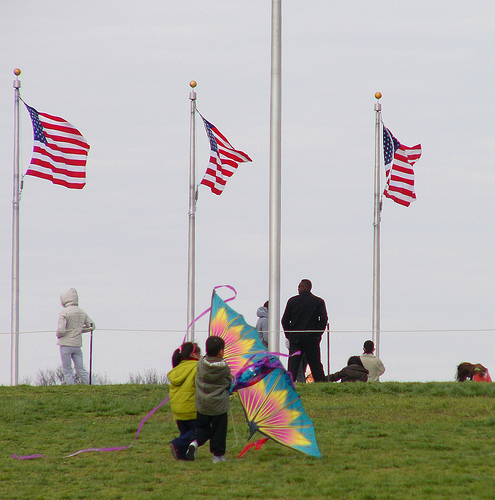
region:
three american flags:
[12, 67, 432, 212]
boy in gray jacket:
[196, 336, 228, 455]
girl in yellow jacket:
[166, 344, 197, 452]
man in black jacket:
[281, 278, 329, 381]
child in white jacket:
[55, 288, 93, 387]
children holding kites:
[166, 285, 326, 463]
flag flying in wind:
[367, 85, 422, 378]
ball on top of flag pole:
[190, 81, 196, 88]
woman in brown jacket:
[337, 355, 368, 382]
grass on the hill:
[7, 388, 490, 494]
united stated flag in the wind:
[13, 91, 96, 187]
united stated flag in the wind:
[190, 103, 269, 205]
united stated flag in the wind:
[375, 116, 430, 218]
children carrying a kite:
[160, 276, 319, 474]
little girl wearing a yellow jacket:
[167, 341, 201, 464]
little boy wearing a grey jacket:
[179, 336, 234, 463]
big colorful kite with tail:
[213, 282, 328, 458]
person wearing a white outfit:
[49, 284, 102, 387]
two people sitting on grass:
[332, 338, 396, 387]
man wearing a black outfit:
[274, 272, 340, 384]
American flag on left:
[22, 103, 91, 189]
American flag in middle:
[198, 116, 253, 196]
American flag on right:
[381, 124, 422, 207]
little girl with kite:
[167, 289, 273, 458]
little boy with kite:
[185, 333, 322, 463]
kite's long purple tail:
[11, 391, 167, 459]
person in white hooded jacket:
[55, 288, 96, 384]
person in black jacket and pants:
[280, 278, 326, 380]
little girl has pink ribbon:
[176, 343, 181, 353]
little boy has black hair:
[205, 336, 224, 355]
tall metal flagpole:
[12, 65, 24, 388]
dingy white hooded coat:
[54, 288, 98, 346]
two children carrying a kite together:
[175, 336, 312, 461]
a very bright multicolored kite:
[211, 293, 324, 458]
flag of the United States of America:
[24, 97, 93, 192]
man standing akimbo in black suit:
[283, 277, 331, 385]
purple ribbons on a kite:
[236, 349, 301, 389]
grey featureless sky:
[0, 5, 491, 384]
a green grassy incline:
[2, 385, 494, 496]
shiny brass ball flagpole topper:
[14, 66, 22, 75]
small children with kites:
[148, 281, 334, 482]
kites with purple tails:
[14, 280, 325, 472]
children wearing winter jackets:
[153, 336, 237, 467]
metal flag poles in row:
[6, 66, 417, 381]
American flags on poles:
[1, 61, 409, 382]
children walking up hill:
[124, 319, 334, 471]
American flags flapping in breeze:
[1, 97, 430, 208]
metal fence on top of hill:
[1, 317, 491, 403]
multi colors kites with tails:
[3, 280, 327, 470]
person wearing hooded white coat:
[47, 287, 102, 385]